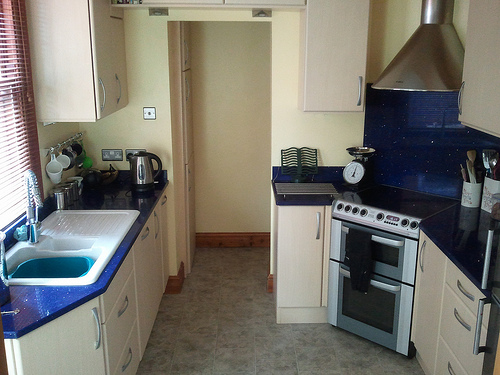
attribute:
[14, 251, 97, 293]
tub — blue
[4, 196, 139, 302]
sink — white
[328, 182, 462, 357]
dutch oven — stainless steel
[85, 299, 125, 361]
handle — metal 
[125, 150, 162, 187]
pot — coffee, electric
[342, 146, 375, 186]
scale — silver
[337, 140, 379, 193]
scale — food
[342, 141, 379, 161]
dial — round, large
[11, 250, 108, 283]
bucket — blue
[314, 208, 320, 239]
handle — metal, silver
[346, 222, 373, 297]
towel — dark dish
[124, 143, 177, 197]
kettle — black, stainless steel 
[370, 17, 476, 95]
exhaust — stainless steel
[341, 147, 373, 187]
scale — stainless steel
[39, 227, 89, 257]
sink — white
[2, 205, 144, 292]
sink — white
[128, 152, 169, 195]
pot — coffee, silver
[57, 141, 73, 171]
cup — white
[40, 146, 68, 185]
cup — white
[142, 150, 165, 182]
handle — black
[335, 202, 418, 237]
dials — round